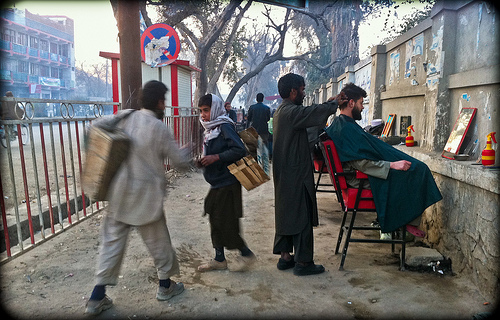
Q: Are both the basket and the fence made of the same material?
A: No, the basket is made of wood and the fence is made of metal.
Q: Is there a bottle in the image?
A: Yes, there is a bottle.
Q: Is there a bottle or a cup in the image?
A: Yes, there is a bottle.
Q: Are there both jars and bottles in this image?
A: No, there is a bottle but no jars.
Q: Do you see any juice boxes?
A: No, there are no juice boxes.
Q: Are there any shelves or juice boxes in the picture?
A: No, there are no juice boxes or shelves.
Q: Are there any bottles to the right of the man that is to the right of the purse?
A: Yes, there is a bottle to the right of the man.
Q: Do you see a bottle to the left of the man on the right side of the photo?
A: No, the bottle is to the right of the man.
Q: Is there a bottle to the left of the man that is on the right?
A: No, the bottle is to the right of the man.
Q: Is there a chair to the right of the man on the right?
A: No, there is a bottle to the right of the man.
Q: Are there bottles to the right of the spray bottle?
A: Yes, there is a bottle to the right of the spray bottle.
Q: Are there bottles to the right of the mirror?
A: Yes, there is a bottle to the right of the mirror.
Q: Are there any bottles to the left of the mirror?
A: No, the bottle is to the right of the mirror.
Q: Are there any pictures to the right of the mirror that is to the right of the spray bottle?
A: No, there is a bottle to the right of the mirror.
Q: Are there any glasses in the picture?
A: No, there are no glasses.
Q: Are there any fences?
A: Yes, there is a fence.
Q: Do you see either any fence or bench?
A: Yes, there is a fence.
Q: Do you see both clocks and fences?
A: No, there is a fence but no clocks.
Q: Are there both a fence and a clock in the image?
A: No, there is a fence but no clocks.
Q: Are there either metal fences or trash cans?
A: Yes, there is a metal fence.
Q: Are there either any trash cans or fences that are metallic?
A: Yes, the fence is metallic.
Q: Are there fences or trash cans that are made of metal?
A: Yes, the fence is made of metal.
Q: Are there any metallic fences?
A: Yes, there is a metal fence.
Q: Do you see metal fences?
A: Yes, there is a metal fence.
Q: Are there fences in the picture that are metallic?
A: Yes, there is a fence that is metallic.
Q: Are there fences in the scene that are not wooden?
A: Yes, there is a metallic fence.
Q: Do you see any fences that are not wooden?
A: Yes, there is a metallic fence.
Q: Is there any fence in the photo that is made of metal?
A: Yes, there is a fence that is made of metal.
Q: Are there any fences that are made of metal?
A: Yes, there is a fence that is made of metal.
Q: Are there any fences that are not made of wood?
A: Yes, there is a fence that is made of metal.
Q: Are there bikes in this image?
A: No, there are no bikes.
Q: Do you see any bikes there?
A: No, there are no bikes.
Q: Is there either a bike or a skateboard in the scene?
A: No, there are no bikes or skateboards.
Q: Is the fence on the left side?
A: Yes, the fence is on the left of the image.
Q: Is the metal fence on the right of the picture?
A: No, the fence is on the left of the image.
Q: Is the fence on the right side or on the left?
A: The fence is on the left of the image.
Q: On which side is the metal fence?
A: The fence is on the left of the image.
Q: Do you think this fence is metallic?
A: Yes, the fence is metallic.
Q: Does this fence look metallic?
A: Yes, the fence is metallic.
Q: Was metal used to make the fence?
A: Yes, the fence is made of metal.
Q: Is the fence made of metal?
A: Yes, the fence is made of metal.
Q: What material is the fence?
A: The fence is made of metal.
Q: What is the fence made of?
A: The fence is made of metal.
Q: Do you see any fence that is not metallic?
A: No, there is a fence but it is metallic.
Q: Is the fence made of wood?
A: No, the fence is made of metal.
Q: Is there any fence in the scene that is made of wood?
A: No, there is a fence but it is made of metal.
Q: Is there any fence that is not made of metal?
A: No, there is a fence but it is made of metal.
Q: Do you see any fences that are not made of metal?
A: No, there is a fence but it is made of metal.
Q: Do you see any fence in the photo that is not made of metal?
A: No, there is a fence but it is made of metal.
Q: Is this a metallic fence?
A: Yes, this is a metallic fence.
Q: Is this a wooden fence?
A: No, this is a metallic fence.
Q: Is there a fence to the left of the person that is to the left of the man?
A: Yes, there is a fence to the left of the person.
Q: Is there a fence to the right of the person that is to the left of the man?
A: No, the fence is to the left of the person.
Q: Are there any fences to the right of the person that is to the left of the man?
A: No, the fence is to the left of the person.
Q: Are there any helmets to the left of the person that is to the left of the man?
A: No, there is a fence to the left of the person.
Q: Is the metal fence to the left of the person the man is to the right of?
A: Yes, the fence is to the left of the person.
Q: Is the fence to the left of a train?
A: No, the fence is to the left of the person.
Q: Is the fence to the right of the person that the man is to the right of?
A: No, the fence is to the left of the person.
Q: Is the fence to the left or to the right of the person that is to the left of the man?
A: The fence is to the left of the person.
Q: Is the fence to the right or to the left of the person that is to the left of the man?
A: The fence is to the left of the person.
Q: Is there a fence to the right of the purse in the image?
A: No, the fence is to the left of the purse.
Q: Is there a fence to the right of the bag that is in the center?
A: No, the fence is to the left of the purse.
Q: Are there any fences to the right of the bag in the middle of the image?
A: No, the fence is to the left of the purse.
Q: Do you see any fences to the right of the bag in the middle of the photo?
A: No, the fence is to the left of the purse.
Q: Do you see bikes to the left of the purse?
A: No, there is a fence to the left of the purse.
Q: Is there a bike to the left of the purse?
A: No, there is a fence to the left of the purse.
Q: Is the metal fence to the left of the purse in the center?
A: Yes, the fence is to the left of the purse.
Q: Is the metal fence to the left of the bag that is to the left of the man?
A: Yes, the fence is to the left of the purse.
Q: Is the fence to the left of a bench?
A: No, the fence is to the left of the purse.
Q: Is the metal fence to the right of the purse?
A: No, the fence is to the left of the purse.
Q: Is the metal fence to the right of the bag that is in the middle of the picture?
A: No, the fence is to the left of the purse.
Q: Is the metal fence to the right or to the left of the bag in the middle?
A: The fence is to the left of the purse.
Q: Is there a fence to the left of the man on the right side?
A: Yes, there is a fence to the left of the man.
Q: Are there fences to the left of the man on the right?
A: Yes, there is a fence to the left of the man.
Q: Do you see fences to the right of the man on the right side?
A: No, the fence is to the left of the man.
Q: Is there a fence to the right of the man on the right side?
A: No, the fence is to the left of the man.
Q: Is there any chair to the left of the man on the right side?
A: No, there is a fence to the left of the man.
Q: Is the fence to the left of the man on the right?
A: Yes, the fence is to the left of the man.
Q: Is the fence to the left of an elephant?
A: No, the fence is to the left of the man.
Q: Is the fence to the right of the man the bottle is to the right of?
A: No, the fence is to the left of the man.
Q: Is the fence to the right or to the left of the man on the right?
A: The fence is to the left of the man.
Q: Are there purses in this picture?
A: Yes, there is a purse.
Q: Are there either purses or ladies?
A: Yes, there is a purse.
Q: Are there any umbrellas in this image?
A: No, there are no umbrellas.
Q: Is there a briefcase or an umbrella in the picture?
A: No, there are no umbrellas or briefcases.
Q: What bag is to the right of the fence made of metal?
A: The bag is a purse.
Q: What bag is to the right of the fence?
A: The bag is a purse.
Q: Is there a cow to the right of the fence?
A: No, there is a purse to the right of the fence.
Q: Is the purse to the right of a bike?
A: No, the purse is to the right of the fence.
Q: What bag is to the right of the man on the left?
A: The bag is a purse.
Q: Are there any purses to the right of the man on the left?
A: Yes, there is a purse to the right of the man.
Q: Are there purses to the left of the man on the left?
A: No, the purse is to the right of the man.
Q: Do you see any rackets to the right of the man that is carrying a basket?
A: No, there is a purse to the right of the man.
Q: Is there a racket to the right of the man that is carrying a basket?
A: No, there is a purse to the right of the man.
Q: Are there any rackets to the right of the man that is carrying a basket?
A: No, there is a purse to the right of the man.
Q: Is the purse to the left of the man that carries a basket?
A: No, the purse is to the right of the man.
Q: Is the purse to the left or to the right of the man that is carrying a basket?
A: The purse is to the right of the man.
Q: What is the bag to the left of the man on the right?
A: The bag is a purse.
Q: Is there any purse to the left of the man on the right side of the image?
A: Yes, there is a purse to the left of the man.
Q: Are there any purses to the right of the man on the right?
A: No, the purse is to the left of the man.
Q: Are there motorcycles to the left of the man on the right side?
A: No, there is a purse to the left of the man.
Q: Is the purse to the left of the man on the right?
A: Yes, the purse is to the left of the man.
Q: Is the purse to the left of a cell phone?
A: No, the purse is to the left of the man.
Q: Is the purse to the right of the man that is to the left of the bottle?
A: No, the purse is to the left of the man.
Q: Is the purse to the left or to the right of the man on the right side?
A: The purse is to the left of the man.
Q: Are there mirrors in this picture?
A: Yes, there is a mirror.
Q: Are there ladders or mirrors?
A: Yes, there is a mirror.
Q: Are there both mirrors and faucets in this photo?
A: No, there is a mirror but no faucets.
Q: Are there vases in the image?
A: No, there are no vases.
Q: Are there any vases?
A: No, there are no vases.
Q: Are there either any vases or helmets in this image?
A: No, there are no vases or helmets.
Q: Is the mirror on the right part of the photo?
A: Yes, the mirror is on the right of the image.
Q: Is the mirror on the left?
A: No, the mirror is on the right of the image.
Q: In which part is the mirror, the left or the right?
A: The mirror is on the right of the image.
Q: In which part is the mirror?
A: The mirror is on the right of the image.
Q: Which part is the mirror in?
A: The mirror is on the right of the image.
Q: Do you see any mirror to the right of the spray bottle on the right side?
A: Yes, there is a mirror to the right of the spray bottle.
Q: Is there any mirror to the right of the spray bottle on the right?
A: Yes, there is a mirror to the right of the spray bottle.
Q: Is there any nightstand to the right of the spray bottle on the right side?
A: No, there is a mirror to the right of the spray bottle.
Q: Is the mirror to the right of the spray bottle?
A: Yes, the mirror is to the right of the spray bottle.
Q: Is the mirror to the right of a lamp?
A: No, the mirror is to the right of the spray bottle.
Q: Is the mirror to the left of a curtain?
A: No, the mirror is to the left of the bottle.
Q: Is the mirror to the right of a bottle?
A: No, the mirror is to the left of a bottle.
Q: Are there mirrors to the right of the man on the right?
A: Yes, there is a mirror to the right of the man.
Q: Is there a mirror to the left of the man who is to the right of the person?
A: No, the mirror is to the right of the man.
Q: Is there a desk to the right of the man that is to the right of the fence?
A: No, there is a mirror to the right of the man.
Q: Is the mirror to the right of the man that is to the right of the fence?
A: Yes, the mirror is to the right of the man.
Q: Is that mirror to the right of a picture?
A: No, the mirror is to the right of the man.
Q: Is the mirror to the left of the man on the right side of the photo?
A: No, the mirror is to the right of the man.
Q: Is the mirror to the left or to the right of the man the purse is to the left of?
A: The mirror is to the right of the man.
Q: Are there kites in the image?
A: No, there are no kites.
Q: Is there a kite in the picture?
A: No, there are no kites.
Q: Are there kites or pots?
A: No, there are no kites or pots.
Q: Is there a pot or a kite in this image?
A: No, there are no kites or pots.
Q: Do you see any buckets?
A: No, there are no buckets.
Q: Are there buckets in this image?
A: No, there are no buckets.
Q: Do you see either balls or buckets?
A: No, there are no buckets or balls.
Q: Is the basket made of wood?
A: Yes, the basket is made of wood.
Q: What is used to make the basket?
A: The basket is made of wood.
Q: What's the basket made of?
A: The basket is made of wood.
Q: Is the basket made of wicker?
A: No, the basket is made of wood.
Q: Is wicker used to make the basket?
A: No, the basket is made of wood.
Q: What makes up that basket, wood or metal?
A: The basket is made of wood.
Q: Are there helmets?
A: No, there are no helmets.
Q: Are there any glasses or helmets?
A: No, there are no helmets or glasses.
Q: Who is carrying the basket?
A: The man is carrying the basket.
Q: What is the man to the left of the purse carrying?
A: The man is carrying a basket.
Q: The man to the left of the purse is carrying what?
A: The man is carrying a basket.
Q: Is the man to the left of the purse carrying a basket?
A: Yes, the man is carrying a basket.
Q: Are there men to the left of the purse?
A: Yes, there is a man to the left of the purse.